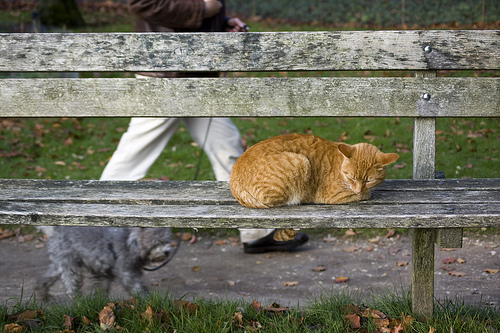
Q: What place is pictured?
A: It is a park.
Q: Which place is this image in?
A: It is at the park.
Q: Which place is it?
A: It is a park.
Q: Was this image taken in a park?
A: Yes, it was taken in a park.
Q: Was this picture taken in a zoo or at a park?
A: It was taken at a park.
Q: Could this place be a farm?
A: No, it is a park.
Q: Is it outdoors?
A: Yes, it is outdoors.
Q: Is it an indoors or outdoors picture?
A: It is outdoors.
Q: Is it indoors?
A: No, it is outdoors.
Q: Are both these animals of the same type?
A: No, they are dogs and cats.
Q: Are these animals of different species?
A: Yes, they are dogs and cats.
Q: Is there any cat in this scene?
A: Yes, there is a cat.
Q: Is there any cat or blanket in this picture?
A: Yes, there is a cat.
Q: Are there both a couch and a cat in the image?
A: No, there is a cat but no couches.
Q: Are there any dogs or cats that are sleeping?
A: Yes, the cat is sleeping.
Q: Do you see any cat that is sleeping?
A: Yes, there is a cat that is sleeping.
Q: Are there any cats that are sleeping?
A: Yes, there is a cat that is sleeping.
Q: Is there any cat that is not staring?
A: Yes, there is a cat that is sleeping.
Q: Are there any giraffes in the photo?
A: No, there are no giraffes.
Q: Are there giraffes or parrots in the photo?
A: No, there are no giraffes or parrots.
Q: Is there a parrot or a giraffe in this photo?
A: No, there are no giraffes or parrots.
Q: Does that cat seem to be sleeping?
A: Yes, the cat is sleeping.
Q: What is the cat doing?
A: The cat is sleeping.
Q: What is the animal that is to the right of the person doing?
A: The cat is sleeping.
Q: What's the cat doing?
A: The cat is sleeping.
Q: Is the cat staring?
A: No, the cat is sleeping.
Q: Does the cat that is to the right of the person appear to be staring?
A: No, the cat is sleeping.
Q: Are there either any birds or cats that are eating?
A: No, there is a cat but it is sleeping.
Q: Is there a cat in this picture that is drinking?
A: No, there is a cat but it is sleeping.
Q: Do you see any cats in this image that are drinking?
A: No, there is a cat but it is sleeping.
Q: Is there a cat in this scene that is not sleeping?
A: No, there is a cat but it is sleeping.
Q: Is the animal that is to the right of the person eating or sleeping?
A: The cat is sleeping.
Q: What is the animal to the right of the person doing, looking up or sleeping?
A: The cat is sleeping.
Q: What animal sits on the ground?
A: The cat sits on the ground.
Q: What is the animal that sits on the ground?
A: The animal is a cat.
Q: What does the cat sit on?
A: The cat sits on the ground.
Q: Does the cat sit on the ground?
A: Yes, the cat sits on the ground.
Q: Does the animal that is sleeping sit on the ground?
A: Yes, the cat sits on the ground.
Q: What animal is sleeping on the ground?
A: The cat is sleeping on the ground.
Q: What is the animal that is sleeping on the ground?
A: The animal is a cat.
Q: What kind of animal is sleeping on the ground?
A: The animal is a cat.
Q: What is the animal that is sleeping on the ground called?
A: The animal is a cat.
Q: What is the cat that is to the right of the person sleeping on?
A: The cat is sleeping on the ground.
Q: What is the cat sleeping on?
A: The cat is sleeping on the ground.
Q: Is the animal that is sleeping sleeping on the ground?
A: Yes, the cat is sleeping on the ground.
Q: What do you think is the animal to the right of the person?
A: The animal is a cat.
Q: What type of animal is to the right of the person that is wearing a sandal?
A: The animal is a cat.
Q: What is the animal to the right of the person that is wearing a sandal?
A: The animal is a cat.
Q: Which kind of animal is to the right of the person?
A: The animal is a cat.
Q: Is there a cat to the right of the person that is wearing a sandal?
A: Yes, there is a cat to the right of the person.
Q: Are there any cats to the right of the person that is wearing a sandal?
A: Yes, there is a cat to the right of the person.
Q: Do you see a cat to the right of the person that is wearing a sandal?
A: Yes, there is a cat to the right of the person.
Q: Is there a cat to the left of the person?
A: No, the cat is to the right of the person.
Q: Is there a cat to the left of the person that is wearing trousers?
A: No, the cat is to the right of the person.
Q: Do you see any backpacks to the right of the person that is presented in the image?
A: No, there is a cat to the right of the person.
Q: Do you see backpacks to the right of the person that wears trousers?
A: No, there is a cat to the right of the person.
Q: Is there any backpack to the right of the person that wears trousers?
A: No, there is a cat to the right of the person.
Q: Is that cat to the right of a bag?
A: No, the cat is to the right of the person.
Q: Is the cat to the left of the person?
A: No, the cat is to the right of the person.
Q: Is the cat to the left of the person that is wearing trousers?
A: No, the cat is to the right of the person.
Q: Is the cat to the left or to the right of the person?
A: The cat is to the right of the person.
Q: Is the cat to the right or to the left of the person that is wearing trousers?
A: The cat is to the right of the person.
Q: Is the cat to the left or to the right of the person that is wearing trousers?
A: The cat is to the right of the person.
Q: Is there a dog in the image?
A: Yes, there is a dog.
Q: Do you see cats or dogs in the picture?
A: Yes, there is a dog.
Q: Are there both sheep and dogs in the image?
A: No, there is a dog but no sheep.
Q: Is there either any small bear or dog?
A: Yes, there is a small dog.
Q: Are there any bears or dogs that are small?
A: Yes, the dog is small.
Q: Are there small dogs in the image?
A: Yes, there is a small dog.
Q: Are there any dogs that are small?
A: Yes, there is a dog that is small.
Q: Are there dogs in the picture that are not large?
A: Yes, there is a small dog.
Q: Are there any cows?
A: No, there are no cows.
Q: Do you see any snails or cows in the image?
A: No, there are no cows or snails.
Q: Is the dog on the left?
A: Yes, the dog is on the left of the image.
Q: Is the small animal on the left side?
A: Yes, the dog is on the left of the image.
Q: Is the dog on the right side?
A: No, the dog is on the left of the image.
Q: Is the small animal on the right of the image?
A: No, the dog is on the left of the image.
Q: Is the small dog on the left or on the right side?
A: The dog is on the left of the image.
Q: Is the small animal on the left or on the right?
A: The dog is on the left of the image.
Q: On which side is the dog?
A: The dog is on the left of the image.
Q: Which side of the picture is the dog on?
A: The dog is on the left of the image.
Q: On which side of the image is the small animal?
A: The dog is on the left of the image.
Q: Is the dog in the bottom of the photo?
A: Yes, the dog is in the bottom of the image.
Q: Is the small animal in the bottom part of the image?
A: Yes, the dog is in the bottom of the image.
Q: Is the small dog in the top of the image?
A: No, the dog is in the bottom of the image.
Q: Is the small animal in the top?
A: No, the dog is in the bottom of the image.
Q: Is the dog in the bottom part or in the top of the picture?
A: The dog is in the bottom of the image.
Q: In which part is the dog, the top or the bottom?
A: The dog is in the bottom of the image.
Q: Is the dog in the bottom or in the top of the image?
A: The dog is in the bottom of the image.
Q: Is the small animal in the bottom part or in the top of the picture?
A: The dog is in the bottom of the image.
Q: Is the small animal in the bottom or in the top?
A: The dog is in the bottom of the image.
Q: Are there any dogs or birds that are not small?
A: No, there is a dog but it is small.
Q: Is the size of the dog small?
A: Yes, the dog is small.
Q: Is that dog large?
A: No, the dog is small.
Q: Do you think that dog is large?
A: No, the dog is small.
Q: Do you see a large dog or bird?
A: No, there is a dog but it is small.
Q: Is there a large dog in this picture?
A: No, there is a dog but it is small.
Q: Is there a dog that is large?
A: No, there is a dog but it is small.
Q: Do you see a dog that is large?
A: No, there is a dog but it is small.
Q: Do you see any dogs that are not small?
A: No, there is a dog but it is small.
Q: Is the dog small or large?
A: The dog is small.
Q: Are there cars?
A: No, there are no cars.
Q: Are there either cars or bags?
A: No, there are no cars or bags.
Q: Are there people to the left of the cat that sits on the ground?
A: Yes, there is a person to the left of the cat.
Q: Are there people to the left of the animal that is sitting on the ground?
A: Yes, there is a person to the left of the cat.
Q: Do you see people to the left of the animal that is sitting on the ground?
A: Yes, there is a person to the left of the cat.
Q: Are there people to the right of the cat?
A: No, the person is to the left of the cat.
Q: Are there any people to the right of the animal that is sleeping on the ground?
A: No, the person is to the left of the cat.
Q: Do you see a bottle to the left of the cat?
A: No, there is a person to the left of the cat.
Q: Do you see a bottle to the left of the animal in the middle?
A: No, there is a person to the left of the cat.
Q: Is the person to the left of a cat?
A: Yes, the person is to the left of a cat.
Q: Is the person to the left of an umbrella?
A: No, the person is to the left of a cat.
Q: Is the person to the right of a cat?
A: No, the person is to the left of a cat.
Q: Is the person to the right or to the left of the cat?
A: The person is to the left of the cat.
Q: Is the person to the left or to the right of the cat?
A: The person is to the left of the cat.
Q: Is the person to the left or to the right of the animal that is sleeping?
A: The person is to the left of the cat.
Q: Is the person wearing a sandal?
A: Yes, the person is wearing a sandal.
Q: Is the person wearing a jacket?
A: No, the person is wearing a sandal.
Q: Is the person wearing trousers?
A: Yes, the person is wearing trousers.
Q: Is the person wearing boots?
A: No, the person is wearing trousers.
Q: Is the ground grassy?
A: Yes, the ground is grassy.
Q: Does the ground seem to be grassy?
A: Yes, the ground is grassy.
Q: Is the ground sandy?
A: No, the ground is grassy.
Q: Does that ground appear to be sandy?
A: No, the ground is grassy.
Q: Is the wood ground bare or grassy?
A: The ground is grassy.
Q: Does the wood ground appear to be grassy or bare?
A: The ground is grassy.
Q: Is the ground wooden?
A: Yes, the ground is wooden.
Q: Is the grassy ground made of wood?
A: Yes, the ground is made of wood.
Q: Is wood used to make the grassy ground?
A: Yes, the ground is made of wood.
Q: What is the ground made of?
A: The ground is made of wood.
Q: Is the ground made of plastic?
A: No, the ground is made of wood.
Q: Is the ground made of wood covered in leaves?
A: Yes, the ground is covered in leaves.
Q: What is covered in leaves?
A: The ground is covered in leaves.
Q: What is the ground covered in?
A: The ground is covered in leaves.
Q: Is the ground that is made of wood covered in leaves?
A: Yes, the ground is covered in leaves.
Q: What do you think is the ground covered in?
A: The ground is covered in leaves.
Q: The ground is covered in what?
A: The ground is covered in leaves.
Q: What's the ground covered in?
A: The ground is covered in leaves.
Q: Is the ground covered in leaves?
A: Yes, the ground is covered in leaves.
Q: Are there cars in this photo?
A: No, there are no cars.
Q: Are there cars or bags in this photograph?
A: No, there are no cars or bags.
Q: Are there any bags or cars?
A: No, there are no cars or bags.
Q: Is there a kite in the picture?
A: No, there are no kites.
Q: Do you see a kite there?
A: No, there are no kites.